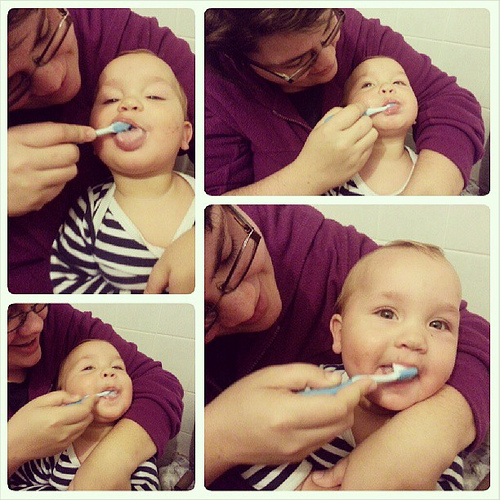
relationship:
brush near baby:
[308, 368, 417, 406] [287, 235, 471, 489]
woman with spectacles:
[205, 6, 485, 196] [237, 8, 348, 86]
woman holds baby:
[205, 6, 485, 196] [287, 235, 471, 489]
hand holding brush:
[215, 362, 361, 464] [294, 363, 417, 397]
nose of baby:
[395, 312, 430, 352] [231, 238, 463, 492]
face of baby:
[50, 336, 134, 423] [4, 337, 163, 488]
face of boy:
[338, 258, 460, 411] [201, 239, 467, 489]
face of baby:
[318, 238, 461, 408] [231, 238, 463, 492]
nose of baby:
[391, 314, 428, 355] [231, 238, 463, 492]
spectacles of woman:
[237, 8, 349, 83] [205, 6, 485, 196]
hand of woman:
[2, 122, 99, 214] [8, 10, 198, 294]